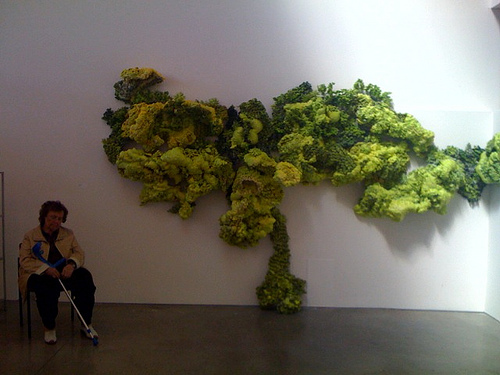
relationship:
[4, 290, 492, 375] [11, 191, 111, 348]
floor under woman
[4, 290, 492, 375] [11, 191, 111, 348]
floor below woman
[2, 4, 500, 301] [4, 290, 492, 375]
wall above floor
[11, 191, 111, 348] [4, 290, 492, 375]
woman above floor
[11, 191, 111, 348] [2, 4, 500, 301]
woman beside wall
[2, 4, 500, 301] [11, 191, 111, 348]
wall behind woman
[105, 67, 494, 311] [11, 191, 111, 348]
art above woman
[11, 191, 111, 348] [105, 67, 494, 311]
woman below art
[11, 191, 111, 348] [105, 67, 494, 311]
woman under art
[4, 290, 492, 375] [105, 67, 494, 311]
floor under art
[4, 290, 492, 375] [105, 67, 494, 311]
floor below art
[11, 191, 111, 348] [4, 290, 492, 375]
woman on floor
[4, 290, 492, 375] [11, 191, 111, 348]
floor near woman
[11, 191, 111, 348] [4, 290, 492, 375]
woman near floor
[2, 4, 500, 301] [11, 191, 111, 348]
wall near woman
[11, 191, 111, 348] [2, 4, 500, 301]
woman near wall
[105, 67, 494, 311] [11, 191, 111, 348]
art near woman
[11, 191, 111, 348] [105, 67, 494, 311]
woman near art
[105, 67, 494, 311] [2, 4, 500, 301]
art on wall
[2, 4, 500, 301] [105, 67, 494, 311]
wall near art